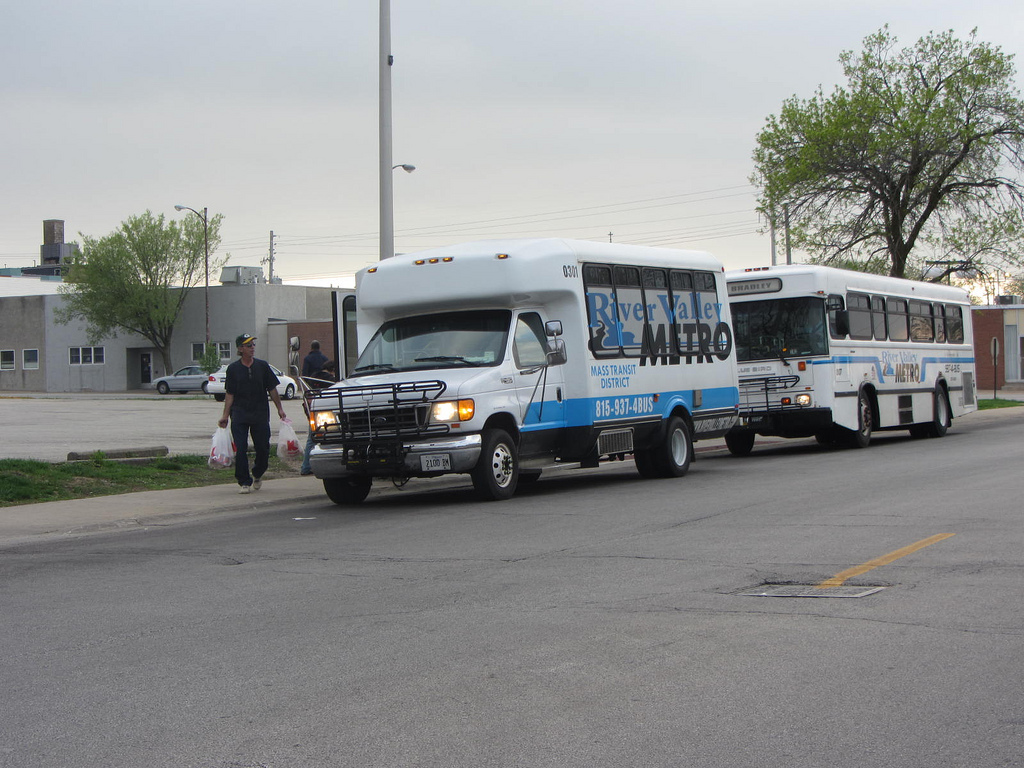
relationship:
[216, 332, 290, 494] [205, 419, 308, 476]
man carrying bags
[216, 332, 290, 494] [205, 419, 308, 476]
man holding bags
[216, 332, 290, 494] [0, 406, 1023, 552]
man on sidewalk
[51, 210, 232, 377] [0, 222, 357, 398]
tree next to building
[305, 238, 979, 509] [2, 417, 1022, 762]
buses alongside road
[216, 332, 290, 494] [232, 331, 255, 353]
man wearing hat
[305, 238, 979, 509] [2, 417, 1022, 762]
buses by road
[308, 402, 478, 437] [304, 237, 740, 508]
lights of buses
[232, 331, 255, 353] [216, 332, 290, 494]
hat on man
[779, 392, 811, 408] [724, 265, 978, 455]
lights on bus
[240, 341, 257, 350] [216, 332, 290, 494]
glasses on man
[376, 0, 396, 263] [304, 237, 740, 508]
pole next to buses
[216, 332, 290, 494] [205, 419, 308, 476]
man with bags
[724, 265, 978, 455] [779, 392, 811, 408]
bus has lights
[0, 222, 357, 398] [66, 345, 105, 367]
building with windows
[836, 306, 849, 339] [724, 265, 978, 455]
mirror of bus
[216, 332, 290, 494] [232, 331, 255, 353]
man has hat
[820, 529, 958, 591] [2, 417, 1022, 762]
line on road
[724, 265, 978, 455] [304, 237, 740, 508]
bus behind buses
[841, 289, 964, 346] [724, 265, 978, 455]
windows on bus